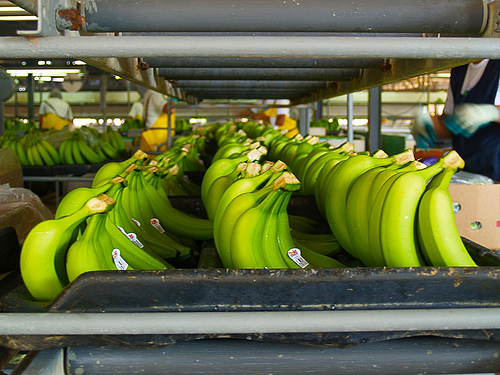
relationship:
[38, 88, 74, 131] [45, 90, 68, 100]
person has hairnet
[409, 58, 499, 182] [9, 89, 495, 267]
person on assembly line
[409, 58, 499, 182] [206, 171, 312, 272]
person standing bananas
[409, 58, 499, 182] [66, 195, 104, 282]
person standing banana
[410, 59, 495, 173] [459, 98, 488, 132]
person wears gloves